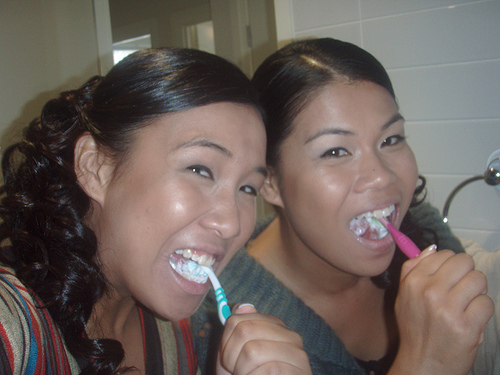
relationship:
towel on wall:
[472, 245, 500, 268] [434, 86, 466, 132]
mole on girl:
[368, 165, 382, 182] [273, 42, 455, 344]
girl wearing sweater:
[273, 42, 455, 344] [250, 268, 300, 308]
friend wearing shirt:
[70, 57, 263, 285] [9, 297, 47, 343]